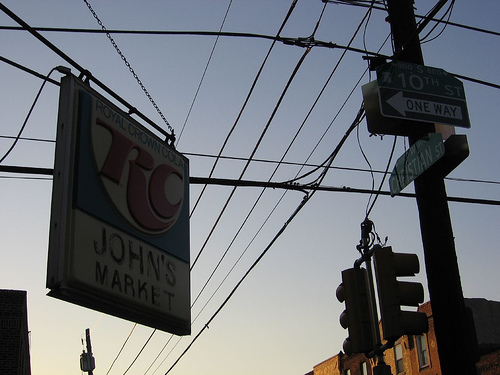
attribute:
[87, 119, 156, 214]
letter — written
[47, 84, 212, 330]
sign — big, business, rc, hanging, green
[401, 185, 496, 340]
pole — thin, tall, wooden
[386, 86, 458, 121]
arrow — white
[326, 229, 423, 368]
traffic lights — grey, hanging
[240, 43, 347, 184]
power lines — black, running, hanging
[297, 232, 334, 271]
cloud — grey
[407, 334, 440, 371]
window — grey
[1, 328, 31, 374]
wall — brick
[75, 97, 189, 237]
rc — royal crown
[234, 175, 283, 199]
wire — long, running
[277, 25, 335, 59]
transformer — black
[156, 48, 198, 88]
sky — blue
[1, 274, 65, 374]
building — brick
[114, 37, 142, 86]
chain — helping